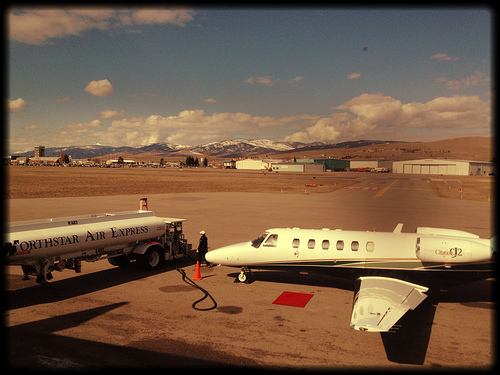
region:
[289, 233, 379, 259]
Six windows on a plane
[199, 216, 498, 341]
A small white plane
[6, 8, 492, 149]
Many white clouds in the sky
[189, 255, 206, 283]
An orange traffic cone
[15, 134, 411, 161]
Mountains in the far distance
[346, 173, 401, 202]
Yellow lines on the tarmac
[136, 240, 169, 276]
A round black tire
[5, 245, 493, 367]
Shadows on the ground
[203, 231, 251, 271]
Nose of a plane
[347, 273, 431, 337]
The wing of an airplane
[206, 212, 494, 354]
white painted small plane with windows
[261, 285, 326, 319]
red square mat on the paved ground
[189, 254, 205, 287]
bright orange safety cone near the plane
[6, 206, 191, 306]
truck with company name painted on it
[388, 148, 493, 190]
large white building with huge doors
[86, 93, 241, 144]
white clouds in the clear blue sky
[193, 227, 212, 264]
person in dark clothes with white hat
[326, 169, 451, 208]
plane runway in between grass lawns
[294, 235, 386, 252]
glass windows on the side of the plane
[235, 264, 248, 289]
small tire supporting the landed plane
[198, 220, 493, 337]
Small jet sitting on the concrete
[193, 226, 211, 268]
Workman standing in front of the airplane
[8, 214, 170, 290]
Gas tanker in front of the jet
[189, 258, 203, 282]
Orange cone in front of the jet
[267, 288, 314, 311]
Red carpet next to the jet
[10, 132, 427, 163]
Grey mountains in the background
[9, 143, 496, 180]
Buildings behind the jet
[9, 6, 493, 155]
White clouds in the sky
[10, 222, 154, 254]
Black writing on the tanker truck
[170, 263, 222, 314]
Gas hose next to the jet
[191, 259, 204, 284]
a orange caution cone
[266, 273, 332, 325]
a red rug on the ground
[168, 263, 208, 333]
a long black hose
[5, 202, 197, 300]
a diesel truck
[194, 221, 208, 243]
a person wearing a white hat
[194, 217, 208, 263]
a person wearing black clothing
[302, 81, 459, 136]
white clouds in the sky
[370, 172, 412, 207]
a yellow line painted on a runway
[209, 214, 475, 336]
a parked air plane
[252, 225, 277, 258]
the cockpit window on plane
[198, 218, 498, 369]
airplane on the tarmac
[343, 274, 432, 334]
a wing of an airplane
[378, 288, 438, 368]
a shadow of the wing of an airplane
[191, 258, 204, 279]
an orange cone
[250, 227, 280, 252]
a cockpit of the airplane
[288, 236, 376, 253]
windows of the airplane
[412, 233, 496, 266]
engine of the plane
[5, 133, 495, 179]
buildings and mountains in the background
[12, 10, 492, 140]
blue sky with clouds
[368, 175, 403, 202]
a yellow line in the tarmac